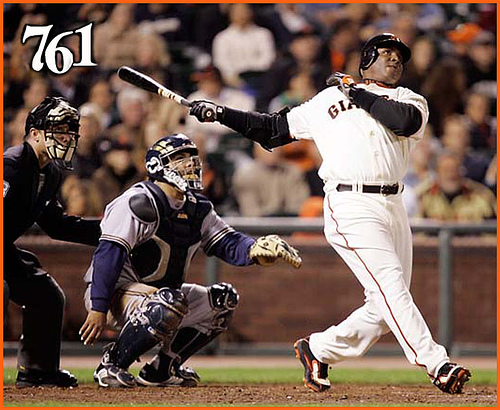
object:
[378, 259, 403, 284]
knee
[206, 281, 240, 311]
pads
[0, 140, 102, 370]
uniform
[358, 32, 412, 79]
helmet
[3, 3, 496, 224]
spectators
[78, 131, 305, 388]
catcher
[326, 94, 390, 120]
lettering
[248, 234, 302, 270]
glove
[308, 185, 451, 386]
pants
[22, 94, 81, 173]
helmet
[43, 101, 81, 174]
face mask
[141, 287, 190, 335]
pads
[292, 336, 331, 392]
shoe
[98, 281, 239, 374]
leg guards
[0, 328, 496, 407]
field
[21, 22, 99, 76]
761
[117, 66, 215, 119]
bat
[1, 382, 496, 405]
dirt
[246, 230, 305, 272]
catchers mitt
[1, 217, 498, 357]
wall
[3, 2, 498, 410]
stadium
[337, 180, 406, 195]
belt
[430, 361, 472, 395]
shoe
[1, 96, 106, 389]
men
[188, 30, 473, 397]
men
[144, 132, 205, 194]
helmets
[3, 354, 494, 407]
ground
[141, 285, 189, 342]
kneepads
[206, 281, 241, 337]
kneepads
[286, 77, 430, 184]
shirt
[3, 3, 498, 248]
stands